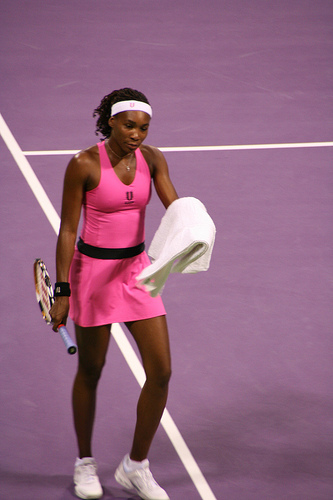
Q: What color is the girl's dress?
A: Pink.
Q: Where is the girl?
A: On the tennis court.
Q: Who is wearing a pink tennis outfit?
A: The tennis player.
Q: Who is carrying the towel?
A: The girl.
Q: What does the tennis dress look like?
A: Pink halter with black band.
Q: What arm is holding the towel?
A: The left.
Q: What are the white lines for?
A: To divide the tennis court.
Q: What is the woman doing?
A: Walking.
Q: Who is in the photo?
A: A female tennis player.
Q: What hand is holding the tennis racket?
A: The right hand.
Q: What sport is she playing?
A: Tennis.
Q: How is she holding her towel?
A: Draped over her arm.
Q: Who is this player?
A: One of the Williams sisters.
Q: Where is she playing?
A: On a purple tennis court.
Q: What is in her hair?
A: A white band.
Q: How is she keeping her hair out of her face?
A: It is in a ponytail and she has a headband.